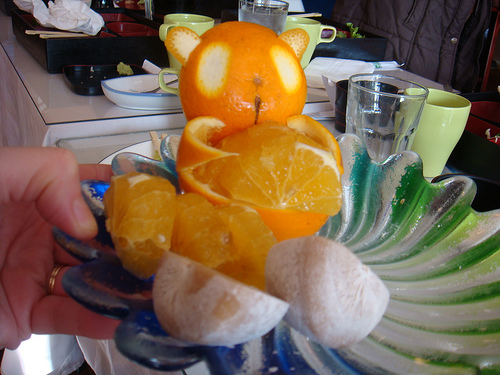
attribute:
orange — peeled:
[196, 115, 351, 212]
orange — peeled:
[260, 232, 395, 353]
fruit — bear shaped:
[105, 15, 389, 349]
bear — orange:
[165, 25, 347, 241]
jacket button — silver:
[451, 36, 458, 44]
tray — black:
[13, 13, 169, 75]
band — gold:
[44, 263, 64, 295]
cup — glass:
[349, 72, 426, 147]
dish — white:
[85, 76, 180, 119]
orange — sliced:
[268, 228, 397, 355]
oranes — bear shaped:
[155, 44, 347, 239]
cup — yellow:
[374, 70, 481, 195]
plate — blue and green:
[50, 131, 498, 373]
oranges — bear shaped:
[89, 10, 426, 372]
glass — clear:
[342, 71, 434, 165]